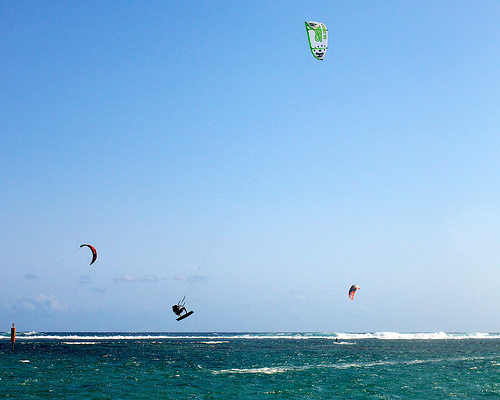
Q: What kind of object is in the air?
A: A kite.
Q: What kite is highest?
A: The green and white kite.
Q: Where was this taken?
A: On the water in the ocean.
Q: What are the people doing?
A: Parasailing.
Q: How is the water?
A: Calm.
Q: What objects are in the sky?
A: Clouds.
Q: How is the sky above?
A: Clear.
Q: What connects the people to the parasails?
A: Cables.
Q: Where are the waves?
A: On the ocean.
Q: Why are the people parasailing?
A: Recreation.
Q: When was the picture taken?
A: During the daytime.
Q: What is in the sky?
A: A kite.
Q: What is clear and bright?
A: A sky.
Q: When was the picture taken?
A: Daytime.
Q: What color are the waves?
A: White.